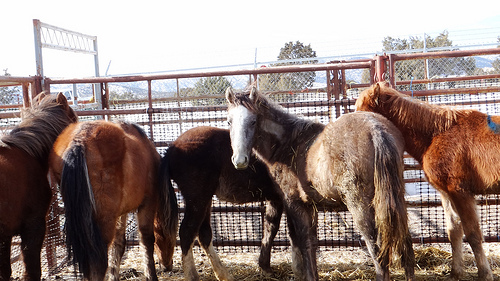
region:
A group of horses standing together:
[3, 85, 498, 257]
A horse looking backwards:
[221, 85, 424, 279]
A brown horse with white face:
[223, 88, 412, 275]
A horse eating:
[56, 114, 186, 279]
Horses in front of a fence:
[3, 63, 497, 277]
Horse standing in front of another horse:
[167, 88, 410, 277]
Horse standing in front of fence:
[226, 70, 399, 269]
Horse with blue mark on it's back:
[356, 85, 498, 270]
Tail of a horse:
[61, 146, 91, 263]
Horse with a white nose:
[226, 87, 261, 177]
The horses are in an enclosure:
[10, 42, 485, 267]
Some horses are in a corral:
[10, 45, 495, 260]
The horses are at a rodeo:
[25, 40, 495, 260]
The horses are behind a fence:
[0, 41, 490, 271]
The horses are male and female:
[17, 61, 484, 269]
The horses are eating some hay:
[28, 20, 493, 236]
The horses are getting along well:
[27, 68, 477, 271]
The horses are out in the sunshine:
[20, 41, 445, 277]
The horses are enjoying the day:
[27, 44, 489, 268]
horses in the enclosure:
[5, 80, 482, 270]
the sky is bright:
[157, 16, 249, 56]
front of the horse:
[216, 90, 256, 163]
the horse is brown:
[430, 135, 478, 175]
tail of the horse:
[47, 135, 108, 217]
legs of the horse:
[160, 227, 232, 277]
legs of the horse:
[290, 225, 421, 277]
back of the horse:
[150, 103, 210, 200]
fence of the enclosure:
[124, 79, 189, 131]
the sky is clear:
[342, 5, 398, 29]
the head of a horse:
[221, 77, 267, 171]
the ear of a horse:
[246, 79, 259, 106]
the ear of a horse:
[222, 83, 237, 105]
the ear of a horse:
[56, 89, 68, 107]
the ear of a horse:
[367, 82, 385, 104]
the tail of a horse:
[367, 126, 405, 273]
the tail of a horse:
[58, 140, 105, 279]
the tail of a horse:
[153, 152, 183, 254]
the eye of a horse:
[247, 115, 260, 130]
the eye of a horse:
[223, 113, 234, 128]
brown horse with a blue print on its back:
[356, 76, 499, 279]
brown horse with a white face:
[223, 84, 412, 278]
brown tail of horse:
[367, 123, 412, 271]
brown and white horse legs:
[168, 173, 233, 280]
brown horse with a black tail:
[48, 121, 177, 280]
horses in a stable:
[1, 49, 498, 278]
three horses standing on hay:
[155, 63, 498, 279]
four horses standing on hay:
[54, 80, 497, 280]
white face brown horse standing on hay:
[221, 81, 424, 279]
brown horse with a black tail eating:
[48, 117, 180, 279]